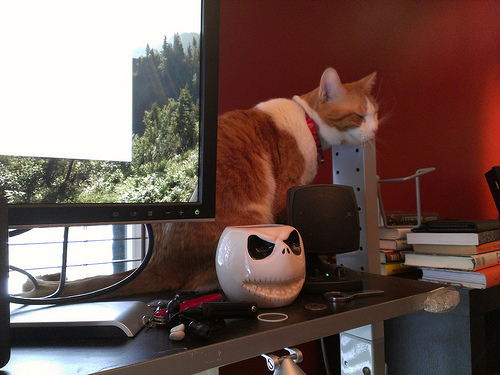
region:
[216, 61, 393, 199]
Orange and white cat rubbing face on table stand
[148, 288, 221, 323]
Red swiss army knife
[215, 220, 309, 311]
Scary skull mug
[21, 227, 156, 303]
Computer cords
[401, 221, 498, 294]
Stack of five books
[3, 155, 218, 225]
Computer monitor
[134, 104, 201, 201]
Screen saver of a forest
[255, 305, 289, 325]
Plain white rubber band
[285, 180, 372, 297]
Small black computer speaker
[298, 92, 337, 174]
Red cat collar with a bell at the end of it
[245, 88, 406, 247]
A brown cat is sitting on the table.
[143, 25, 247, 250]
The monitor or television is on.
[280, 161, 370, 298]
A black speaker on the desk.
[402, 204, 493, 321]
Books stacked in the corner.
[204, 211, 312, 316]
A black and white ceramic object next to the cat.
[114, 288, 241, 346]
A pocket knife on the table.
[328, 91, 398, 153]
The cat has long whiskers.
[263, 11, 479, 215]
The wall is orange.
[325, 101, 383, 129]
The cat's eyes are closed.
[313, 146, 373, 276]
Holes in the iron rod.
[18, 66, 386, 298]
Orange and white cat rubbing its face against a post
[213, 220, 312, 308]
white skeleton mug with black eyes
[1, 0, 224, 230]
flat screen computer monitor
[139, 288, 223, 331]
red swiss army knife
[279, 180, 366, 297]
black computer speaker with two knobs on it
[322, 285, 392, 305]
silver and gray key lying on shelf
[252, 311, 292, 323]
small light pink circular rubber band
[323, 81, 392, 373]
white metal post with small holes in it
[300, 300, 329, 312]
silver quarter lying on the shelf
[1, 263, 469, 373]
gray stone shelf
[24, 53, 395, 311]
brown and white cat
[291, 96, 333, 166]
red coolar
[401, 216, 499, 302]
stack of five books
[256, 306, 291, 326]
white hair band on the table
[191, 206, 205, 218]
power button is lit up yellow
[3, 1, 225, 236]
monitor is turned on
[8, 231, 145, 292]
light streaming in through the window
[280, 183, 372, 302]
black speaker with a tiny green light on it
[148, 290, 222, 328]
deep red pocket knife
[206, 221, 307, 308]
white and black bowl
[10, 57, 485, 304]
cat sitting next to screen on desk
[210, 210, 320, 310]
scary black and white ceramic container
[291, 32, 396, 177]
cat rubbing neck on metal pole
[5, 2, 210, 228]
nature scene on screen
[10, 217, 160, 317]
thick black wire under monitor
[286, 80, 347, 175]
red collar around cat neck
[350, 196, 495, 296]
two piles of books on table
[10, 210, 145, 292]
sunlight coming through slatted window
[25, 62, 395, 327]
orange and white cat on black desk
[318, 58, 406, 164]
cat face with eyes closed